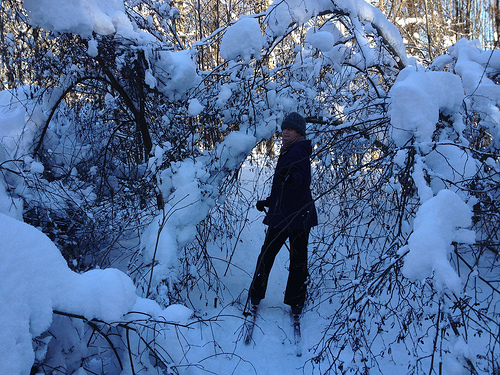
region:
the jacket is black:
[273, 144, 333, 295]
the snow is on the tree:
[421, 195, 460, 260]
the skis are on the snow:
[235, 311, 311, 360]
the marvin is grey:
[280, 114, 317, 134]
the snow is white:
[401, 76, 443, 121]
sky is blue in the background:
[413, 1, 490, 17]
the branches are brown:
[399, 9, 480, 42]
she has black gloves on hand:
[241, 195, 273, 215]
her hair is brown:
[287, 123, 309, 143]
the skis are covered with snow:
[241, 307, 326, 373]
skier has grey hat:
[279, 113, 309, 135]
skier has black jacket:
[265, 140, 319, 227]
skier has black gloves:
[252, 194, 270, 211]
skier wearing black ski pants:
[250, 228, 315, 309]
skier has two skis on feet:
[241, 305, 311, 360]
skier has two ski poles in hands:
[245, 170, 294, 283]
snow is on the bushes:
[1, 0, 497, 374]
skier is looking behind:
[245, 112, 310, 353]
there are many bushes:
[1, 1, 498, 371]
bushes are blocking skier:
[6, 1, 498, 373]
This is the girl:
[244, 115, 320, 318]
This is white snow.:
[16, 265, 118, 312]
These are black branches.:
[353, 285, 438, 355]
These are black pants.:
[240, 217, 326, 309]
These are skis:
[236, 285, 303, 360]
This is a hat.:
[277, 109, 313, 137]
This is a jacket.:
[258, 137, 327, 239]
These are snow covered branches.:
[29, 169, 226, 356]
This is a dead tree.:
[59, 7, 172, 190]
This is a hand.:
[255, 190, 265, 214]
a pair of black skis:
[239, 301, 309, 360]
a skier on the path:
[230, 111, 320, 341]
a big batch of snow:
[2, 217, 129, 374]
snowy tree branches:
[38, 32, 228, 319]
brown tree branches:
[406, 11, 496, 55]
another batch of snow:
[386, 62, 461, 174]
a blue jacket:
[257, 152, 321, 237]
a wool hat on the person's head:
[275, 106, 300, 128]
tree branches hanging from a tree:
[327, 166, 408, 369]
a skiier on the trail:
[248, 107, 320, 362]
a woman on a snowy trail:
[235, 110, 327, 367]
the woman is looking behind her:
[263, 111, 323, 177]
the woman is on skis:
[238, 287, 309, 356]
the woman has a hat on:
[279, 109, 313, 136]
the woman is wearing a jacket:
[262, 140, 321, 228]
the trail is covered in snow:
[240, 165, 313, 373]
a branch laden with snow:
[0, 207, 191, 374]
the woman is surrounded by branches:
[316, 26, 495, 373]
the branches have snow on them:
[315, 26, 496, 371]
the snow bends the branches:
[315, 37, 497, 364]